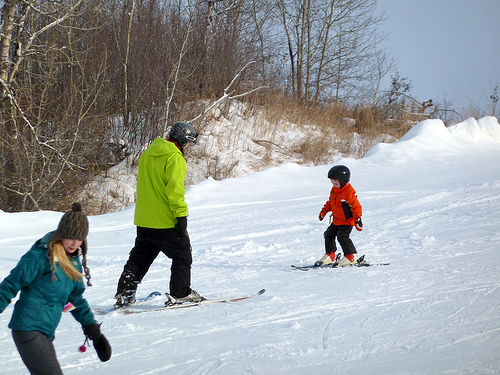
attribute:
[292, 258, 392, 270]
skis — black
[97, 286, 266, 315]
skis — adult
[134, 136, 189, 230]
jacket — green, bright neon green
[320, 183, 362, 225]
coat — orange, red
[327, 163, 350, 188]
helmet — black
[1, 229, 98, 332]
coat — blue, teal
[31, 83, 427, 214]
grass — dead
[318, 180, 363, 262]
ski outfit — orange, black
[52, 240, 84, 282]
hair — blonde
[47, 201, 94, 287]
hat — knit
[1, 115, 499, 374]
snow — white, very white, super white, bright white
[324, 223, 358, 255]
snow pants — black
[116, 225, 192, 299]
snow pants — black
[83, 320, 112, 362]
glove — black